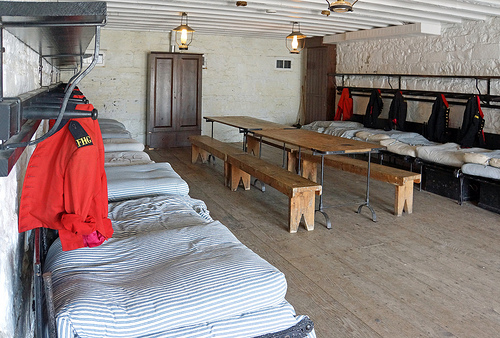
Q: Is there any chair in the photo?
A: No, there are no chairs.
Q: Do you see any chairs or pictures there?
A: No, there are no chairs or pictures.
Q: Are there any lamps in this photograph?
A: Yes, there is a lamp.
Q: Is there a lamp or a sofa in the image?
A: Yes, there is a lamp.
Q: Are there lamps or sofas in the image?
A: Yes, there is a lamp.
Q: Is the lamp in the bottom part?
A: No, the lamp is in the top of the image.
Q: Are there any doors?
A: Yes, there is a door.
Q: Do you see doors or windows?
A: Yes, there is a door.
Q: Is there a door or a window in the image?
A: Yes, there is a door.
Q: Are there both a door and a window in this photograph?
A: No, there is a door but no windows.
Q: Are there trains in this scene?
A: No, there are no trains.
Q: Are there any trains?
A: No, there are no trains.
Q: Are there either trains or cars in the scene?
A: No, there are no trains or cars.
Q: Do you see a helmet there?
A: No, there are no helmets.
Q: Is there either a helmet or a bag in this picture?
A: No, there are no helmets or bags.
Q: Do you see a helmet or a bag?
A: No, there are no helmets or bags.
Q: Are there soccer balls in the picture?
A: No, there are no soccer balls.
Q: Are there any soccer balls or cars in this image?
A: No, there are no soccer balls or cars.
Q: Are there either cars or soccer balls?
A: No, there are no soccer balls or cars.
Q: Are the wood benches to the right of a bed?
A: Yes, the benches are to the right of a bed.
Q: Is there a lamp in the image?
A: Yes, there is a lamp.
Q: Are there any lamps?
A: Yes, there is a lamp.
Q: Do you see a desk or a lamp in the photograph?
A: Yes, there is a lamp.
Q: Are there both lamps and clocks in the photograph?
A: No, there is a lamp but no clocks.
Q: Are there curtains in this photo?
A: No, there are no curtains.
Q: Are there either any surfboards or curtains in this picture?
A: No, there are no curtains or surfboards.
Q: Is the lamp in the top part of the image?
A: Yes, the lamp is in the top of the image.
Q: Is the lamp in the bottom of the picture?
A: No, the lamp is in the top of the image.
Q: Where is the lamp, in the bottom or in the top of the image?
A: The lamp is in the top of the image.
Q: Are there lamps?
A: Yes, there is a lamp.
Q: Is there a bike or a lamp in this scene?
A: Yes, there is a lamp.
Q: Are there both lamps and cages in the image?
A: No, there is a lamp but no cages.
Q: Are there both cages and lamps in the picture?
A: No, there is a lamp but no cages.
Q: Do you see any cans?
A: No, there are no cans.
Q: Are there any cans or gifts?
A: No, there are no cans or gifts.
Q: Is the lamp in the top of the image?
A: Yes, the lamp is in the top of the image.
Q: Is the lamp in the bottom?
A: No, the lamp is in the top of the image.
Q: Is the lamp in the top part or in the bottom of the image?
A: The lamp is in the top of the image.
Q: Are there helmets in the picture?
A: No, there are no helmets.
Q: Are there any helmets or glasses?
A: No, there are no helmets or glasses.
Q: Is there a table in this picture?
A: Yes, there is a table.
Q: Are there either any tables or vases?
A: Yes, there is a table.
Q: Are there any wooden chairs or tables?
A: Yes, there is a wood table.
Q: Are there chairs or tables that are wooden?
A: Yes, the table is wooden.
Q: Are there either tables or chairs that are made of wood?
A: Yes, the table is made of wood.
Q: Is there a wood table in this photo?
A: Yes, there is a wood table.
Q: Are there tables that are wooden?
A: Yes, there is a table that is wooden.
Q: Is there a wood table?
A: Yes, there is a table that is made of wood.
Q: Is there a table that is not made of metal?
A: Yes, there is a table that is made of wood.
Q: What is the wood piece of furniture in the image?
A: The piece of furniture is a table.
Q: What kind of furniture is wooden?
A: The furniture is a table.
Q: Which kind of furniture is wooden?
A: The furniture is a table.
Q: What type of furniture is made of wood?
A: The furniture is a table.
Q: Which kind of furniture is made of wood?
A: The furniture is a table.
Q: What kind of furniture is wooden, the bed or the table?
A: The table is wooden.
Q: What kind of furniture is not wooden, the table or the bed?
A: The bed is not wooden.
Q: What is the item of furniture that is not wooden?
A: The piece of furniture is a bed.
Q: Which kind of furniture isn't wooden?
A: The furniture is a bed.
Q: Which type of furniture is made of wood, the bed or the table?
A: The table is made of wood.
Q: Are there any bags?
A: No, there are no bags.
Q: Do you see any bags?
A: No, there are no bags.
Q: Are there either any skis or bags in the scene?
A: No, there are no bags or skis.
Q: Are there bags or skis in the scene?
A: No, there are no bags or skis.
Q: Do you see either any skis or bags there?
A: No, there are no bags or skis.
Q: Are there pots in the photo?
A: No, there are no pots.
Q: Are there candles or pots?
A: No, there are no pots or candles.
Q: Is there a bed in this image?
A: Yes, there is a bed.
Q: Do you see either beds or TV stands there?
A: Yes, there is a bed.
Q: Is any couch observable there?
A: No, there are no couches.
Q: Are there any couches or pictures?
A: No, there are no couches or pictures.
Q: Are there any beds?
A: Yes, there is a bed.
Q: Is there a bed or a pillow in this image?
A: Yes, there is a bed.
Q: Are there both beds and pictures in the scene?
A: No, there is a bed but no pictures.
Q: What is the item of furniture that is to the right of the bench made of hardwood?
A: The piece of furniture is a bed.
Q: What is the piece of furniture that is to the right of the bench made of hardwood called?
A: The piece of furniture is a bed.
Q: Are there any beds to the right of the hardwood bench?
A: Yes, there is a bed to the right of the bench.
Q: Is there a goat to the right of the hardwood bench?
A: No, there is a bed to the right of the bench.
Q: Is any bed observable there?
A: Yes, there is a bed.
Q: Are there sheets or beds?
A: Yes, there is a bed.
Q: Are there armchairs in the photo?
A: No, there are no armchairs.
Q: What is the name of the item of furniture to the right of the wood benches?
A: The piece of furniture is a bed.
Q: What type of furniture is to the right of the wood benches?
A: The piece of furniture is a bed.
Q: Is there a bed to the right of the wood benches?
A: Yes, there is a bed to the right of the benches.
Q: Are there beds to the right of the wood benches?
A: Yes, there is a bed to the right of the benches.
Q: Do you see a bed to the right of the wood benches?
A: Yes, there is a bed to the right of the benches.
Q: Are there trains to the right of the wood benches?
A: No, there is a bed to the right of the benches.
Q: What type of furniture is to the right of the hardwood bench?
A: The piece of furniture is a bed.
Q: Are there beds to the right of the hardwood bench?
A: Yes, there is a bed to the right of the bench.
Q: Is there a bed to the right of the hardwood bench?
A: Yes, there is a bed to the right of the bench.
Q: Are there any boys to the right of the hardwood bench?
A: No, there is a bed to the right of the bench.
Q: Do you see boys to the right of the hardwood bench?
A: No, there is a bed to the right of the bench.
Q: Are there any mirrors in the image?
A: No, there are no mirrors.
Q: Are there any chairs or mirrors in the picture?
A: No, there are no mirrors or chairs.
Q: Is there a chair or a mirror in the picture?
A: No, there are no mirrors or chairs.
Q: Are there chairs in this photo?
A: No, there are no chairs.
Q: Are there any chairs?
A: No, there are no chairs.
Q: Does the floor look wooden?
A: Yes, the floor is wooden.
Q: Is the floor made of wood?
A: Yes, the floor is made of wood.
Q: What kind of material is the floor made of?
A: The floor is made of wood.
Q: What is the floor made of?
A: The floor is made of wood.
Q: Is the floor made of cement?
A: No, the floor is made of wood.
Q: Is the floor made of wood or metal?
A: The floor is made of wood.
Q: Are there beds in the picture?
A: Yes, there is a bed.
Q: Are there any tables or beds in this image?
A: Yes, there is a bed.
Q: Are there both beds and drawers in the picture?
A: No, there is a bed but no drawers.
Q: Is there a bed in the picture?
A: Yes, there is a bed.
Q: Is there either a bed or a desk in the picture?
A: Yes, there is a bed.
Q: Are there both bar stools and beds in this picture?
A: No, there is a bed but no bar stools.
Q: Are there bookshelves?
A: No, there are no bookshelves.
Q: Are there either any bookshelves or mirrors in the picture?
A: No, there are no bookshelves or mirrors.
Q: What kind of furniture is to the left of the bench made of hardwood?
A: The piece of furniture is a bed.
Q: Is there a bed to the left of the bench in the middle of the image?
A: Yes, there is a bed to the left of the bench.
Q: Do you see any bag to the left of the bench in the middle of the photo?
A: No, there is a bed to the left of the bench.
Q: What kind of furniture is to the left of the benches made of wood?
A: The piece of furniture is a bed.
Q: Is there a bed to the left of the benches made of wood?
A: Yes, there is a bed to the left of the benches.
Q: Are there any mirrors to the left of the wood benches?
A: No, there is a bed to the left of the benches.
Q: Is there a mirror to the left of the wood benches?
A: No, there is a bed to the left of the benches.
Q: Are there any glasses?
A: No, there are no glasses.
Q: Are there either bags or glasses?
A: No, there are no glasses or bags.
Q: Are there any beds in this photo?
A: Yes, there is a bed.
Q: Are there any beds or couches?
A: Yes, there is a bed.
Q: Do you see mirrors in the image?
A: No, there are no mirrors.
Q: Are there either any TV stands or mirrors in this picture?
A: No, there are no mirrors or TV stands.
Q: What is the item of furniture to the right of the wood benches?
A: The piece of furniture is a bed.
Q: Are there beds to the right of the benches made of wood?
A: Yes, there is a bed to the right of the benches.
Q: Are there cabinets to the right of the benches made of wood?
A: No, there is a bed to the right of the benches.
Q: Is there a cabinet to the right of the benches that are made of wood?
A: No, there is a bed to the right of the benches.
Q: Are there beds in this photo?
A: Yes, there is a bed.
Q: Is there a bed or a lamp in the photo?
A: Yes, there is a bed.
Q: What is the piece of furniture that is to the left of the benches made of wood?
A: The piece of furniture is a bed.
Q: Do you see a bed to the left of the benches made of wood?
A: Yes, there is a bed to the left of the benches.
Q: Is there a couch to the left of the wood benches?
A: No, there is a bed to the left of the benches.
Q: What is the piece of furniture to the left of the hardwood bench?
A: The piece of furniture is a bed.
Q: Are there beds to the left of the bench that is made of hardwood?
A: Yes, there is a bed to the left of the bench.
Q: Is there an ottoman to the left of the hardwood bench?
A: No, there is a bed to the left of the bench.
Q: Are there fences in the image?
A: No, there are no fences.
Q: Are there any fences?
A: No, there are no fences.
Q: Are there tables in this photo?
A: Yes, there is a table.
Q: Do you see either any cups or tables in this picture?
A: Yes, there is a table.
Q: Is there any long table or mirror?
A: Yes, there is a long table.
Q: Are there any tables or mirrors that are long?
A: Yes, the table is long.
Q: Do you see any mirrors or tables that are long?
A: Yes, the table is long.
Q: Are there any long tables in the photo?
A: Yes, there is a long table.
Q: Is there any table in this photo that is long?
A: Yes, there is a table that is long.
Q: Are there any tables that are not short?
A: Yes, there is a long table.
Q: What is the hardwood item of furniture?
A: The piece of furniture is a table.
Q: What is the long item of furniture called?
A: The piece of furniture is a table.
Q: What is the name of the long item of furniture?
A: The piece of furniture is a table.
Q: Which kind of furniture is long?
A: The furniture is a table.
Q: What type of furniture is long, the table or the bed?
A: The table is long.